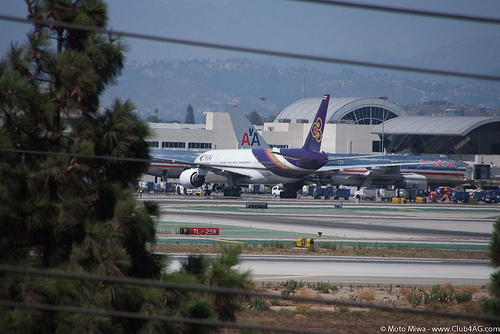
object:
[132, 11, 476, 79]
sky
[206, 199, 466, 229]
runway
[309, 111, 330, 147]
logo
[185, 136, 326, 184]
plane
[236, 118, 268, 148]
logo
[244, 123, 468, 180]
plane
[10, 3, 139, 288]
tree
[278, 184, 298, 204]
wheels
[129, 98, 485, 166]
building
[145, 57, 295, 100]
mountain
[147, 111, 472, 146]
airport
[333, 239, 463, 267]
grass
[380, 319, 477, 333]
writing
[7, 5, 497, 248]
photo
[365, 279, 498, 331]
corner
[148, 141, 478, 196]
airplanes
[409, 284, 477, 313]
plants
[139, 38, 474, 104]
mountains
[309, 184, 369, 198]
luggage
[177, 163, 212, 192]
engine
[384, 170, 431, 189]
engine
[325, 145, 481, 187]
airplane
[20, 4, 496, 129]
background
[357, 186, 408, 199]
vehicles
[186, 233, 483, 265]
ground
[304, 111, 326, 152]
design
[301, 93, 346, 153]
tail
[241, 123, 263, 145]
design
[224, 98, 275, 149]
tail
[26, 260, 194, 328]
fence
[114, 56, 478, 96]
hills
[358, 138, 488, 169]
gate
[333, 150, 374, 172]
midsection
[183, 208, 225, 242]
sign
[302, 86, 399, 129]
window